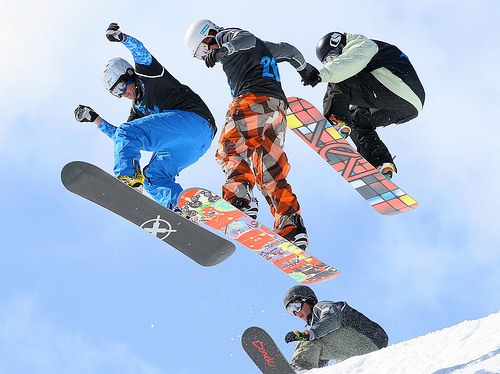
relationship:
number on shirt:
[259, 53, 280, 80] [216, 26, 307, 107]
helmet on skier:
[183, 19, 220, 61] [183, 16, 323, 249]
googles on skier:
[193, 35, 213, 59] [183, 16, 323, 249]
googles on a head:
[111, 79, 130, 99] [101, 54, 141, 102]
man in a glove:
[182, 16, 322, 252] [203, 46, 226, 68]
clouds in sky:
[3, 291, 163, 371] [2, 3, 490, 372]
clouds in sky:
[278, 3, 477, 302] [2, 3, 490, 372]